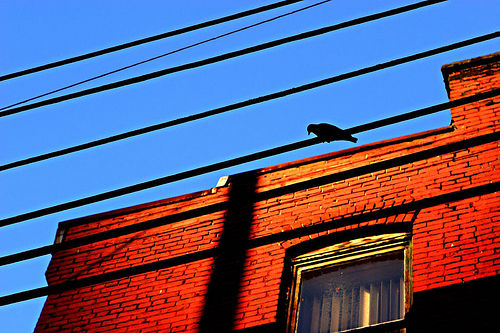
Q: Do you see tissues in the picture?
A: No, there are no tissues.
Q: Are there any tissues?
A: No, there are no tissues.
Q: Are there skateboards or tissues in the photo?
A: No, there are no tissues or skateboards.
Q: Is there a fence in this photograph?
A: No, there are no fences.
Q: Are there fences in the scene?
A: No, there are no fences.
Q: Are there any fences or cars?
A: No, there are no fences or cars.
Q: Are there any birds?
A: Yes, there is a bird.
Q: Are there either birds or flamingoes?
A: Yes, there is a bird.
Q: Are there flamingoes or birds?
A: Yes, there is a bird.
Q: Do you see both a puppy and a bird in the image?
A: No, there is a bird but no puppies.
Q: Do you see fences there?
A: No, there are no fences.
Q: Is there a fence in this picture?
A: No, there are no fences.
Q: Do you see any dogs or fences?
A: No, there are no fences or dogs.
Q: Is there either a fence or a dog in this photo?
A: No, there are no fences or dogs.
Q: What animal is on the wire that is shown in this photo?
A: The bird is on the wire.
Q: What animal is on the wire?
A: The animal is a bird.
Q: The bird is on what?
A: The bird is on the wire.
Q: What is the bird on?
A: The bird is on the wire.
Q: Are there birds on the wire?
A: Yes, there is a bird on the wire.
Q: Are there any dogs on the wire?
A: No, there is a bird on the wire.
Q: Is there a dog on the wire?
A: No, there is a bird on the wire.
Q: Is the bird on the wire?
A: Yes, the bird is on the wire.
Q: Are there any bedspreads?
A: No, there are no bedspreads.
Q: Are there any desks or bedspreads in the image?
A: No, there are no bedspreads or desks.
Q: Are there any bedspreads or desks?
A: No, there are no bedspreads or desks.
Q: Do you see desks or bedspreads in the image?
A: No, there are no bedspreads or desks.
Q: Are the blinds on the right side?
A: Yes, the blinds are on the right of the image.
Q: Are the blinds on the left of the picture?
A: No, the blinds are on the right of the image.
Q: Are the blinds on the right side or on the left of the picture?
A: The blinds are on the right of the image.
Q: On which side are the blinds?
A: The blinds are on the right of the image.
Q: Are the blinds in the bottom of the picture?
A: Yes, the blinds are in the bottom of the image.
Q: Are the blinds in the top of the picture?
A: No, the blinds are in the bottom of the image.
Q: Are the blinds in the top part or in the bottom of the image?
A: The blinds are in the bottom of the image.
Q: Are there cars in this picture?
A: No, there are no cars.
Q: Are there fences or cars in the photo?
A: No, there are no cars or fences.